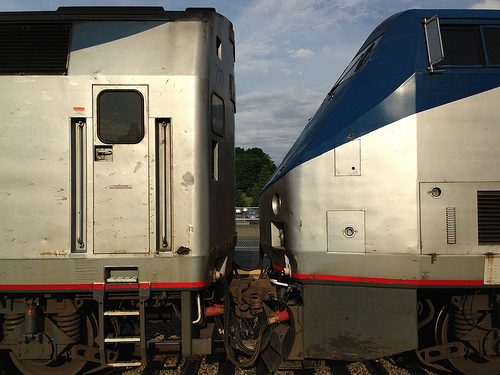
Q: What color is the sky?
A: Blue.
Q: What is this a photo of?
A: A train.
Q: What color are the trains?
A: Blue and silver.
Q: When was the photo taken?
A: Daytime.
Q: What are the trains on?
A: Rails.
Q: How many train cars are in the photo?
A: Two.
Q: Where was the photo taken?
A: At a train station.